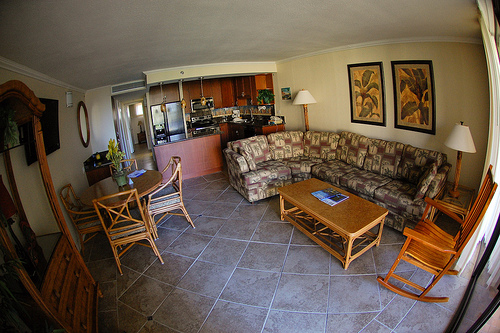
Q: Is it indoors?
A: Yes, it is indoors.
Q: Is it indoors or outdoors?
A: It is indoors.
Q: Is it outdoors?
A: No, it is indoors.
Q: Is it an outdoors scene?
A: No, it is indoors.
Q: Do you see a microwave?
A: Yes, there is a microwave.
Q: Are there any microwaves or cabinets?
A: Yes, there is a microwave.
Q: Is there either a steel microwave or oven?
A: Yes, there is a steel microwave.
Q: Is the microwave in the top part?
A: Yes, the microwave is in the top of the image.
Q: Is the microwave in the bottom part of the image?
A: No, the microwave is in the top of the image.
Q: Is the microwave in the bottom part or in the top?
A: The microwave is in the top of the image.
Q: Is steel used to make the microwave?
A: Yes, the microwave is made of steel.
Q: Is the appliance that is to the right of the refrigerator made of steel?
A: Yes, the microwave is made of steel.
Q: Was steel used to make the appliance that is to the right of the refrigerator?
A: Yes, the microwave is made of steel.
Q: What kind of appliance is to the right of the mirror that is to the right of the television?
A: The appliance is a microwave.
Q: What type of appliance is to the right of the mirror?
A: The appliance is a microwave.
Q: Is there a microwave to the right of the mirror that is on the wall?
A: Yes, there is a microwave to the right of the mirror.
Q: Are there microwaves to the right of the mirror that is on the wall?
A: Yes, there is a microwave to the right of the mirror.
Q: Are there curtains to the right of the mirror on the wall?
A: No, there is a microwave to the right of the mirror.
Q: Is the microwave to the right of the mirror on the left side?
A: Yes, the microwave is to the right of the mirror.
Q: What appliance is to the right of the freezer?
A: The appliance is a microwave.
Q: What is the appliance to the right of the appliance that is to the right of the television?
A: The appliance is a microwave.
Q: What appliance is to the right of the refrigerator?
A: The appliance is a microwave.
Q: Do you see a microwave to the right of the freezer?
A: Yes, there is a microwave to the right of the freezer.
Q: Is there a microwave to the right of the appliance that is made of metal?
A: Yes, there is a microwave to the right of the freezer.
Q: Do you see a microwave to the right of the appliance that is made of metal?
A: Yes, there is a microwave to the right of the freezer.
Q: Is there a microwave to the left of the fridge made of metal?
A: No, the microwave is to the right of the fridge.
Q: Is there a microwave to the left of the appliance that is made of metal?
A: No, the microwave is to the right of the fridge.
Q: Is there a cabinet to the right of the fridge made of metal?
A: No, there is a microwave to the right of the freezer.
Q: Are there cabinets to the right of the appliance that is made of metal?
A: No, there is a microwave to the right of the freezer.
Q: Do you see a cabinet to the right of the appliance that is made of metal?
A: No, there is a microwave to the right of the freezer.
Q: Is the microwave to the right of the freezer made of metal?
A: Yes, the microwave is to the right of the refrigerator.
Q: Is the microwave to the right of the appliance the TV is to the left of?
A: Yes, the microwave is to the right of the refrigerator.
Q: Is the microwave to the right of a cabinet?
A: No, the microwave is to the right of the refrigerator.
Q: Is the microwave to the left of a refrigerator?
A: No, the microwave is to the right of a refrigerator.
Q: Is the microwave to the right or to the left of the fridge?
A: The microwave is to the right of the fridge.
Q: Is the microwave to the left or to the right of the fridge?
A: The microwave is to the right of the fridge.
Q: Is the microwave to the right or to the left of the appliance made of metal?
A: The microwave is to the right of the fridge.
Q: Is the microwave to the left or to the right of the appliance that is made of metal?
A: The microwave is to the right of the fridge.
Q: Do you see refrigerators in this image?
A: Yes, there is a refrigerator.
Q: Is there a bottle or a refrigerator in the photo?
A: Yes, there is a refrigerator.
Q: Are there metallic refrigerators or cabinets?
A: Yes, there is a metal refrigerator.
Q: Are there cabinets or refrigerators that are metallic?
A: Yes, the refrigerator is metallic.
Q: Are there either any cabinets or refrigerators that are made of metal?
A: Yes, the refrigerator is made of metal.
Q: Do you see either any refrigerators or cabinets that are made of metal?
A: Yes, the refrigerator is made of metal.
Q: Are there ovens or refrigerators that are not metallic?
A: No, there is a refrigerator but it is metallic.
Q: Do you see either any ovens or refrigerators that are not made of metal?
A: No, there is a refrigerator but it is made of metal.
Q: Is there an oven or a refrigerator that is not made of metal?
A: No, there is a refrigerator but it is made of metal.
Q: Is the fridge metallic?
A: Yes, the fridge is metallic.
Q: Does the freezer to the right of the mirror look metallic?
A: Yes, the refrigerator is metallic.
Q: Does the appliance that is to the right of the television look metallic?
A: Yes, the refrigerator is metallic.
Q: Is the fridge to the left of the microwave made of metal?
A: Yes, the fridge is made of metal.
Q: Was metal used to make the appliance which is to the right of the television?
A: Yes, the fridge is made of metal.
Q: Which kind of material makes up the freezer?
A: The freezer is made of metal.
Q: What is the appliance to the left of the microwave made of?
A: The freezer is made of metal.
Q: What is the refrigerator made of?
A: The freezer is made of metal.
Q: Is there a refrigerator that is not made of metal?
A: No, there is a refrigerator but it is made of metal.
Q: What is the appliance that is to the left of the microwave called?
A: The appliance is a refrigerator.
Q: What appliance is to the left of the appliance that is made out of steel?
A: The appliance is a refrigerator.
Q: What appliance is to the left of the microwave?
A: The appliance is a refrigerator.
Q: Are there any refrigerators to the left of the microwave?
A: Yes, there is a refrigerator to the left of the microwave.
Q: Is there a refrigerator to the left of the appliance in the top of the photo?
A: Yes, there is a refrigerator to the left of the microwave.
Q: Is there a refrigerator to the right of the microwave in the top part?
A: No, the refrigerator is to the left of the microwave.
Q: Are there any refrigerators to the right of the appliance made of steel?
A: No, the refrigerator is to the left of the microwave.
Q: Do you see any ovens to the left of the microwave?
A: No, there is a refrigerator to the left of the microwave.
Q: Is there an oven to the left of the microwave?
A: No, there is a refrigerator to the left of the microwave.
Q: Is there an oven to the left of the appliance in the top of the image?
A: No, there is a refrigerator to the left of the microwave.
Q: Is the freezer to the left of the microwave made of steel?
A: Yes, the freezer is to the left of the microwave.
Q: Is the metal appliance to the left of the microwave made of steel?
A: Yes, the freezer is to the left of the microwave.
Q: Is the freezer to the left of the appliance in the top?
A: Yes, the freezer is to the left of the microwave.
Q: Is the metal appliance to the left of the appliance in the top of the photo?
A: Yes, the freezer is to the left of the microwave.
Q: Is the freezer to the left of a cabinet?
A: No, the freezer is to the left of the microwave.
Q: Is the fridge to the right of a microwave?
A: No, the fridge is to the left of a microwave.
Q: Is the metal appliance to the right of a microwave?
A: No, the fridge is to the left of a microwave.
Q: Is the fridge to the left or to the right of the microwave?
A: The fridge is to the left of the microwave.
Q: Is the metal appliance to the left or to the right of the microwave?
A: The fridge is to the left of the microwave.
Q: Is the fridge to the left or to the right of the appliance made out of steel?
A: The fridge is to the left of the microwave.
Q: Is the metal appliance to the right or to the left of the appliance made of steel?
A: The fridge is to the left of the microwave.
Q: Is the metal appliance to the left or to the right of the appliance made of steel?
A: The fridge is to the left of the microwave.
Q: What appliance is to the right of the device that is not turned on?
A: The appliance is a refrigerator.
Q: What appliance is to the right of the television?
A: The appliance is a refrigerator.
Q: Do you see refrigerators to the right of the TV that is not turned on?
A: Yes, there is a refrigerator to the right of the TV.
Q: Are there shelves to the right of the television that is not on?
A: No, there is a refrigerator to the right of the television.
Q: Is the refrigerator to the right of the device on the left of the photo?
A: Yes, the refrigerator is to the right of the TV.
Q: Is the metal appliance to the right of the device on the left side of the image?
A: Yes, the refrigerator is to the right of the TV.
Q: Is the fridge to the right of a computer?
A: No, the fridge is to the right of the TV.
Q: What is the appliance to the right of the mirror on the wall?
A: The appliance is a refrigerator.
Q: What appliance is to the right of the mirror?
A: The appliance is a refrigerator.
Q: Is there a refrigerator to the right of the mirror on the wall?
A: Yes, there is a refrigerator to the right of the mirror.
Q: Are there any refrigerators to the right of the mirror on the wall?
A: Yes, there is a refrigerator to the right of the mirror.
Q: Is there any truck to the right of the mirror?
A: No, there is a refrigerator to the right of the mirror.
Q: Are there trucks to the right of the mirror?
A: No, there is a refrigerator to the right of the mirror.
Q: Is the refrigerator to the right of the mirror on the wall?
A: Yes, the refrigerator is to the right of the mirror.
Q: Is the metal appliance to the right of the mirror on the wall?
A: Yes, the refrigerator is to the right of the mirror.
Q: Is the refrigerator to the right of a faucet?
A: No, the refrigerator is to the right of the mirror.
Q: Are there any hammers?
A: No, there are no hammers.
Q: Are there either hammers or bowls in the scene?
A: No, there are no hammers or bowls.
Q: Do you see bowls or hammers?
A: No, there are no hammers or bowls.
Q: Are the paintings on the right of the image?
A: Yes, the paintings are on the right of the image.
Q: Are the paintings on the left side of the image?
A: No, the paintings are on the right of the image.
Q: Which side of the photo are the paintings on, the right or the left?
A: The paintings are on the right of the image.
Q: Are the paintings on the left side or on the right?
A: The paintings are on the right of the image.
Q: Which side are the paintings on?
A: The paintings are on the right of the image.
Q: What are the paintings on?
A: The paintings are on the wall.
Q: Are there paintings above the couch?
A: Yes, there are paintings above the couch.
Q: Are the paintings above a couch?
A: Yes, the paintings are above a couch.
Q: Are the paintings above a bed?
A: No, the paintings are above a couch.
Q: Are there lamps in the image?
A: Yes, there is a lamp.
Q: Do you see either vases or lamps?
A: Yes, there is a lamp.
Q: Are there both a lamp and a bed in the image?
A: No, there is a lamp but no beds.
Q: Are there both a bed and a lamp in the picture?
A: No, there is a lamp but no beds.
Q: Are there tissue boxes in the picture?
A: No, there are no tissue boxes.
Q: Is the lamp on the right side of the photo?
A: Yes, the lamp is on the right of the image.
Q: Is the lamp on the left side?
A: No, the lamp is on the right of the image.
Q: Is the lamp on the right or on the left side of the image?
A: The lamp is on the right of the image.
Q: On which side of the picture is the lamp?
A: The lamp is on the right of the image.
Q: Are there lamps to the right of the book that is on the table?
A: Yes, there is a lamp to the right of the book.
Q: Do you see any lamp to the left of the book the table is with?
A: No, the lamp is to the right of the book.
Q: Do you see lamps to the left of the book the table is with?
A: No, the lamp is to the right of the book.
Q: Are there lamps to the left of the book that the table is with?
A: No, the lamp is to the right of the book.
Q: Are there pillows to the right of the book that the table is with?
A: No, there is a lamp to the right of the book.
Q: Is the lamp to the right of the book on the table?
A: Yes, the lamp is to the right of the book.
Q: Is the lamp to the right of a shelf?
A: No, the lamp is to the right of the book.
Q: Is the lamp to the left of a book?
A: No, the lamp is to the right of a book.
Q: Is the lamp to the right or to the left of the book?
A: The lamp is to the right of the book.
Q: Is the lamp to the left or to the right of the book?
A: The lamp is to the right of the book.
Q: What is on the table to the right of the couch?
A: The lamp is on the table.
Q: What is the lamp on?
A: The lamp is on the table.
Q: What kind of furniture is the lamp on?
A: The lamp is on the table.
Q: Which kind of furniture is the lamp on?
A: The lamp is on the table.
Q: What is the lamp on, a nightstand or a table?
A: The lamp is on a table.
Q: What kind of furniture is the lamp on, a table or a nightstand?
A: The lamp is on a table.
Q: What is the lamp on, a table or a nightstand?
A: The lamp is on a table.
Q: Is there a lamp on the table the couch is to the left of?
A: Yes, there is a lamp on the table.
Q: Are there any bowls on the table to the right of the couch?
A: No, there is a lamp on the table.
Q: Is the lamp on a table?
A: Yes, the lamp is on a table.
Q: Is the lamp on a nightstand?
A: No, the lamp is on a table.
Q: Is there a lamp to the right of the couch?
A: Yes, there is a lamp to the right of the couch.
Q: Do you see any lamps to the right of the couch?
A: Yes, there is a lamp to the right of the couch.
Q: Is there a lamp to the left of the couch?
A: No, the lamp is to the right of the couch.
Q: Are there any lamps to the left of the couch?
A: No, the lamp is to the right of the couch.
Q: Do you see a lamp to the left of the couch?
A: No, the lamp is to the right of the couch.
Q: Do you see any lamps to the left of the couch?
A: No, the lamp is to the right of the couch.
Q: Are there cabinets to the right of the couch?
A: No, there is a lamp to the right of the couch.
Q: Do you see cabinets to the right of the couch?
A: No, there is a lamp to the right of the couch.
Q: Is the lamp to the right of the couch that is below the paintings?
A: Yes, the lamp is to the right of the couch.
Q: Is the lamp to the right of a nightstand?
A: No, the lamp is to the right of the couch.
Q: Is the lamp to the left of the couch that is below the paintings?
A: No, the lamp is to the right of the couch.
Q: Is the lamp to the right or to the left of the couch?
A: The lamp is to the right of the couch.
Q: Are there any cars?
A: No, there are no cars.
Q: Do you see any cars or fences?
A: No, there are no cars or fences.